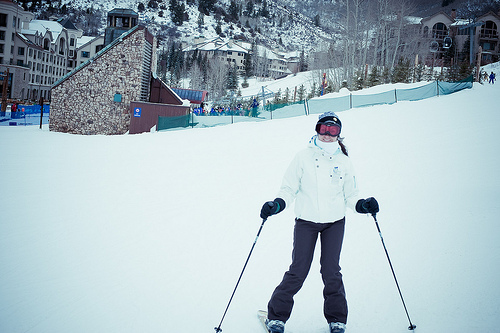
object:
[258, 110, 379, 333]
woman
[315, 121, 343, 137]
goggles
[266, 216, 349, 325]
pants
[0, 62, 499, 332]
snow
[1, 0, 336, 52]
mountains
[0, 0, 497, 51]
snow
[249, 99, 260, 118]
people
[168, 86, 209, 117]
building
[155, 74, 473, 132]
fence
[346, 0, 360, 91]
tree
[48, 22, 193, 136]
building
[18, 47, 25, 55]
window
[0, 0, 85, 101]
building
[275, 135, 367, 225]
coat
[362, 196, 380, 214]
hand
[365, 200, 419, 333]
ski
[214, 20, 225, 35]
tree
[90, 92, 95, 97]
stone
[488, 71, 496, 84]
kids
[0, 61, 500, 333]
ground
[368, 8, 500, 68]
ski lodge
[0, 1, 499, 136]
background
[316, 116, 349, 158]
hair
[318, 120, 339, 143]
face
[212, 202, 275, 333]
pole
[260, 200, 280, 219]
hand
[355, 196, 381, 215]
glove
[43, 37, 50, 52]
window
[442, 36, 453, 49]
ski lift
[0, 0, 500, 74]
air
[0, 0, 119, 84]
upper left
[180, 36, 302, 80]
apartments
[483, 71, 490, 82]
person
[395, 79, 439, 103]
mesh